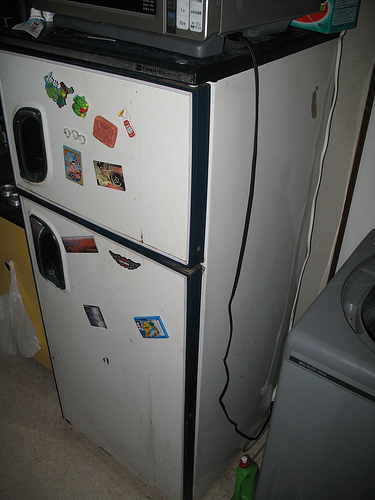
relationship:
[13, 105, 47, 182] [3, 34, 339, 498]
handle with freezer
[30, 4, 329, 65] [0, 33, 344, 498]
microwave on side of freezer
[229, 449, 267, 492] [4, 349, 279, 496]
detergent bottle on floor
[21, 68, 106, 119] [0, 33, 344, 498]
stickers on freezer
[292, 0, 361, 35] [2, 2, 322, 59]
soap box behind microwave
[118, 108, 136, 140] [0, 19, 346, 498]
magnet on refrigerator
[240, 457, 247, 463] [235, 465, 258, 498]
cap is on green bottle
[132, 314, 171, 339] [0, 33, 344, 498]
magnet is on freezer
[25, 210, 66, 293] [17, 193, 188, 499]
door handle is on door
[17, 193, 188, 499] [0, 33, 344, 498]
door is on freezer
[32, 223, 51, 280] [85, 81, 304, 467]
door handle for refriderator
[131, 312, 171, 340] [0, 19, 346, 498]
magnet for refrigerator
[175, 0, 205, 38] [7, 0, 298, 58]
button menu on microwave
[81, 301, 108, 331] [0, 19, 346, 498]
magnet on refrigerator